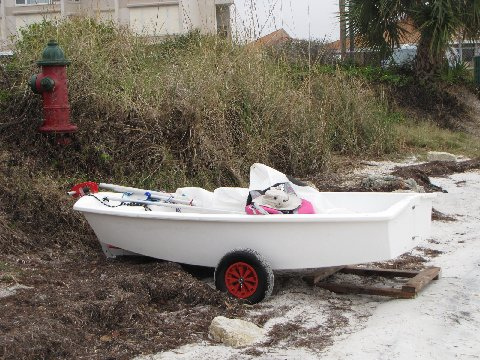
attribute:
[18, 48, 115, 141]
hydrant — red, green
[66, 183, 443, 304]
boat — small, white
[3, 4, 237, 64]
house — white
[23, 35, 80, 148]
fire hydrant — green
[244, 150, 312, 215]
hat — white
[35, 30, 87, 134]
hydrant — red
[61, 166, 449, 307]
dingy — white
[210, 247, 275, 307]
wheel — red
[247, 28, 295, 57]
roof — brown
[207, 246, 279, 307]
tire — back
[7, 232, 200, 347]
dirt — brown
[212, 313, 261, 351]
rock — white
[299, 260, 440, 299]
frame — wooden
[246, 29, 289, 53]
roof — tan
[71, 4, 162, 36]
building — large, cement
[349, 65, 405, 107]
plants — multiple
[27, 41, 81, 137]
hydrant — red, green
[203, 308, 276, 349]
boulder — white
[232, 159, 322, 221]
item — pink, white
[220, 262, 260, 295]
rim — red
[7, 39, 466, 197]
slope — small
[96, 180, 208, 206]
pole — metal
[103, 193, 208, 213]
pole — metal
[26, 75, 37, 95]
opening — green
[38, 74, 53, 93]
opening — green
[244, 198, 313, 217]
stuff — pink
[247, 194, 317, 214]
stuff — pink